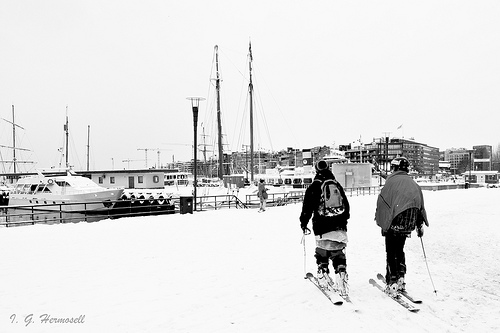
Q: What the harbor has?
A: Boats.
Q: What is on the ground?
A: White snow.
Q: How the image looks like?
A: White and black.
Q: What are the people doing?
A: Skiing.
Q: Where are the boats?
A: In the harbor.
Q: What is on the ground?
A: Snow.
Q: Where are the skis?
A: On the people's feet.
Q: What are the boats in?
A: The water.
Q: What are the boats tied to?
A: The docks.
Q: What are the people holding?
A: Poles.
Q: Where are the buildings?
A: In the back.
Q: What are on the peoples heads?
A: Hats.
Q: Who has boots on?
A: The skiers.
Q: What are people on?
A: Skis.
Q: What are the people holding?
A: Ski poles.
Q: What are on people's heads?
A: Hats.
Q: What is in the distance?
A: Buildings.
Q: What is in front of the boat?
A: Railing.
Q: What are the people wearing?
A: Coats.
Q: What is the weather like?
A: Snowy.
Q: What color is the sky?
A: White.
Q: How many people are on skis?
A: Two.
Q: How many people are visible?
A: Three.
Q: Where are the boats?
A: In water.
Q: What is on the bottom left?
A: A name.